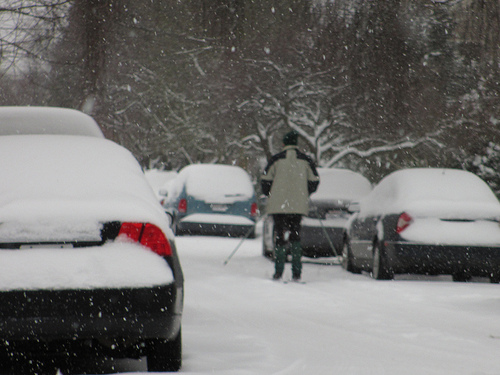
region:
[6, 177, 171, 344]
Black car covered in snow.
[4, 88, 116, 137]
Car covered in snow.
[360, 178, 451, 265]
Dark car covered in snow.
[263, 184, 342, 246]
Car covered in snow.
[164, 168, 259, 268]
Blue car covered in snow.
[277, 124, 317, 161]
Person wearing dark hat.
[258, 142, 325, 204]
Person gray and black coat.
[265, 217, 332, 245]
Person wearing black pants.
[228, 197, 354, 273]
Person holding 2 poles.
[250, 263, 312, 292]
Person has snow shoes on.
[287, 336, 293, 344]
the snow is white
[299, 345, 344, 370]
the snow is white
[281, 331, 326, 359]
the snow is white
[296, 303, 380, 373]
the snow is white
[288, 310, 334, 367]
the snow is white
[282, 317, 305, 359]
the snow is white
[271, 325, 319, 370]
the snow is white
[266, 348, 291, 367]
the snow is white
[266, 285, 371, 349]
snow on the ground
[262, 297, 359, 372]
white snow onthe ground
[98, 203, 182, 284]
red light on the background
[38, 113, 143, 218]
snow on the car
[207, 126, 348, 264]
man with a black and gray coat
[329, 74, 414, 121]
trees next to cars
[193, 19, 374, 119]
trees with no leaves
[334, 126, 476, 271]
two parked cars next to man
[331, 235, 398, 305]
tire of the car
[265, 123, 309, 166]
hat on the man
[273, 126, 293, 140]
Person wearing black hat.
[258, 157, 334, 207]
Person wearing gray and black coat.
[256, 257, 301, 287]
Person wearing snow shoes.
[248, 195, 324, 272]
Person is holding 2 poles.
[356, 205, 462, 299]
Dark car covered in snow.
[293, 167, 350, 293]
Car covered in snow.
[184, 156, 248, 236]
Blue car covered in snow.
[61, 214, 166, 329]
Black car covered in snow.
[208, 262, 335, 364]
Ground is covered in snow.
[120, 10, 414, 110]
It is snowing in the picture.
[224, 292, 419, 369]
Snow is on the ground.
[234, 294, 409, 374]
The snow is white.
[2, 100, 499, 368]
Snow is on the cars.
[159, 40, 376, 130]
Snow is on the trees.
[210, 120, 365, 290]
A person is skiing in the snow.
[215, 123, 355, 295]
The person is wearing a brown top.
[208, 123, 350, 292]
The person is holding ski poles.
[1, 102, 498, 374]
A row of cars.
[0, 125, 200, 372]
The car is black.